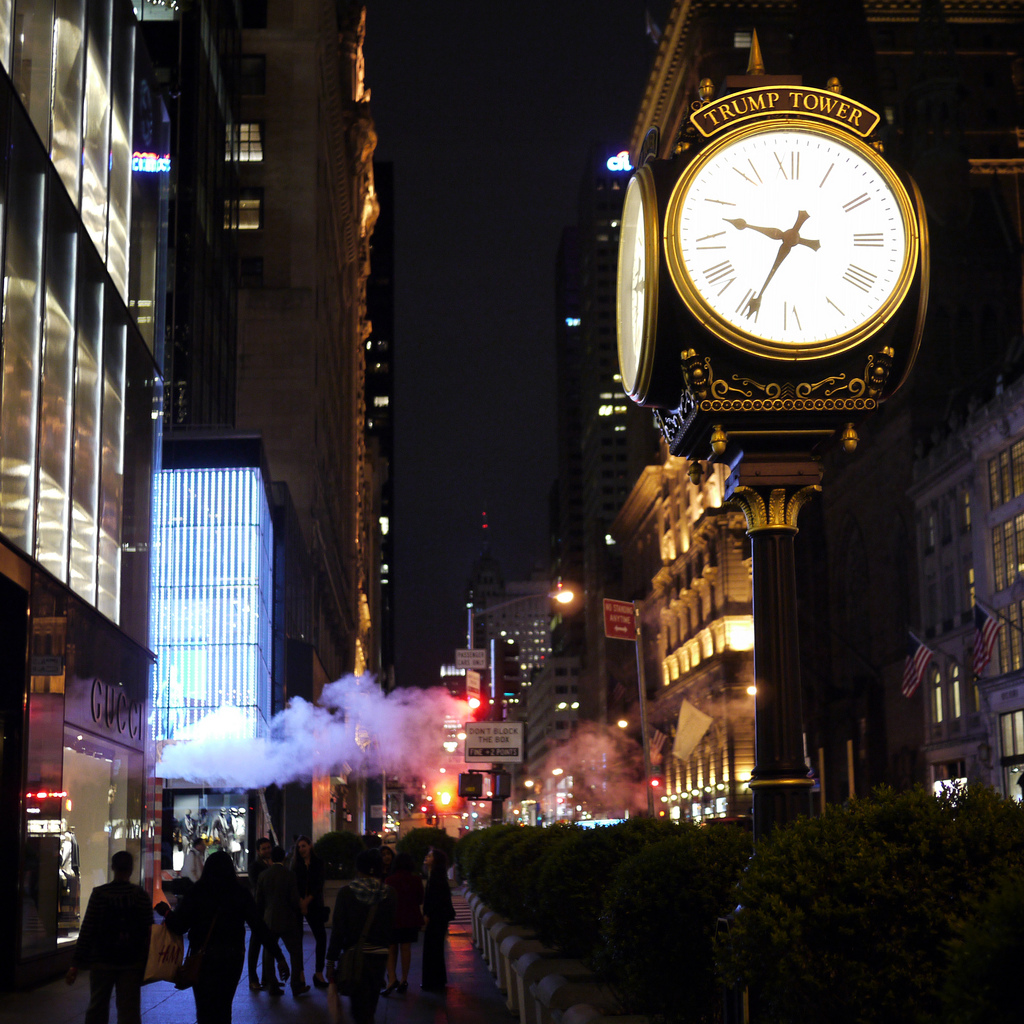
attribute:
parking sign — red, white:
[600, 592, 639, 635]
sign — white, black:
[461, 717, 526, 766]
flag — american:
[871, 632, 992, 708]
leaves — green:
[616, 865, 718, 973]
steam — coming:
[171, 651, 498, 797]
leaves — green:
[822, 832, 922, 896]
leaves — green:
[856, 813, 915, 868]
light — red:
[440, 665, 505, 765]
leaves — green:
[572, 912, 605, 938]